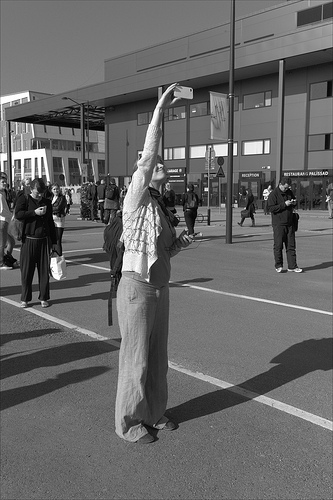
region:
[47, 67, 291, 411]
people on the road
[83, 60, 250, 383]
a person holding a phone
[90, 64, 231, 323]
a man holding a cell phone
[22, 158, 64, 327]
a person wearing a bag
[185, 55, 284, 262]
a banner on a pole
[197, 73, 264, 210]
a ban on a metal pole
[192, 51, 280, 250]
a pole with banner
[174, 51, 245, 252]
a metal pole with banner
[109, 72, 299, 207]
windows on a building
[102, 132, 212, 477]
woman wearing linen pants and ruffled sweater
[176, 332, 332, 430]
shadow of woman cast on the pavement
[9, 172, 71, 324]
woman in black using cellular phone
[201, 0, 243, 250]
tall black post with banner on it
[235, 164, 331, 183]
signs for store and restaurant on street front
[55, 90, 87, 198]
tall black street light on sidewalk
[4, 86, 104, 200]
large white building with many windows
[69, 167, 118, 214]
group of people walking through street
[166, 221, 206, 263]
corded electronics in woman's left hand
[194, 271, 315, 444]
white stripes painted on paved road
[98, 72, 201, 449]
woman taking a selfie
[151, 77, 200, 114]
hand holding a cell phone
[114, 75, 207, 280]
woman wearing a sweater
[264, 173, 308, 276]
man wearing black cloths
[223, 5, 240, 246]
big pole in front a building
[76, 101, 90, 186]
a column behind a building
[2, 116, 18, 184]
a column in corner of building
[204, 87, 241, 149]
a banner on a pole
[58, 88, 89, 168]
a light street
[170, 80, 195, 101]
a white cell phone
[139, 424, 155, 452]
aprt of a shoe